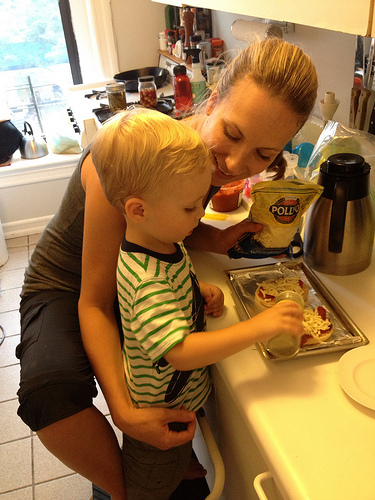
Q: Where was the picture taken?
A: It was taken at the kitchen.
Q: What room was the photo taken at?
A: It was taken at the kitchen.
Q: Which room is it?
A: It is a kitchen.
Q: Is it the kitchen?
A: Yes, it is the kitchen.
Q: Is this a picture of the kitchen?
A: Yes, it is showing the kitchen.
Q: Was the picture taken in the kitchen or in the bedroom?
A: It was taken at the kitchen.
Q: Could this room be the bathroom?
A: No, it is the kitchen.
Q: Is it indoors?
A: Yes, it is indoors.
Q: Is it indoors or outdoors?
A: It is indoors.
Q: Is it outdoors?
A: No, it is indoors.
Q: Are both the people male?
A: No, they are both male and female.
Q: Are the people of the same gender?
A: No, they are both male and female.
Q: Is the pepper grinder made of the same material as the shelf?
A: Yes, both the pepper grinder and the shelf are made of wood.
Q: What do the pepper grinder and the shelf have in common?
A: The material, both the pepper grinder and the shelf are wooden.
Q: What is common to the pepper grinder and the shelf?
A: The material, both the pepper grinder and the shelf are wooden.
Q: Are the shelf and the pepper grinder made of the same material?
A: Yes, both the shelf and the pepper grinder are made of wood.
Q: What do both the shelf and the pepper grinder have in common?
A: The material, both the shelf and the pepper grinder are wooden.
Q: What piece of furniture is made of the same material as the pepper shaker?
A: The shelf is made of the same material as the pepper shaker.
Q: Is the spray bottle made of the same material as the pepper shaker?
A: No, the spray bottle is made of plastic and the pepper shaker is made of wood.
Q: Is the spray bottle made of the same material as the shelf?
A: No, the spray bottle is made of plastic and the shelf is made of wood.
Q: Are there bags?
A: Yes, there is a bag.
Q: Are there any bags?
A: Yes, there is a bag.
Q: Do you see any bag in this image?
A: Yes, there is a bag.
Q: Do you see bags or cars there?
A: Yes, there is a bag.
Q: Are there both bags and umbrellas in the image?
A: No, there is a bag but no umbrellas.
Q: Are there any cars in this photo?
A: No, there are no cars.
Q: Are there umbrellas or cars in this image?
A: No, there are no cars or umbrellas.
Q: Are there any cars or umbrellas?
A: No, there are no cars or umbrellas.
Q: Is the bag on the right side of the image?
A: Yes, the bag is on the right of the image.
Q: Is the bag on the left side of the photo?
A: No, the bag is on the right of the image.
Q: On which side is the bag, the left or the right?
A: The bag is on the right of the image.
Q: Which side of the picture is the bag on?
A: The bag is on the right of the image.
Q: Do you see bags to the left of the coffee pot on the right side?
A: Yes, there is a bag to the left of the coffee pot.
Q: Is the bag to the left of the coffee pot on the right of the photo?
A: Yes, the bag is to the left of the coffee pot.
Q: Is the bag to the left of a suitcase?
A: No, the bag is to the left of the coffee pot.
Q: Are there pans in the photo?
A: Yes, there is a pan.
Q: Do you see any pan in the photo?
A: Yes, there is a pan.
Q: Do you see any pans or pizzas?
A: Yes, there is a pan.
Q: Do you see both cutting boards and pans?
A: No, there is a pan but no cutting boards.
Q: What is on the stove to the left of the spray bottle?
A: The pan is on the stove.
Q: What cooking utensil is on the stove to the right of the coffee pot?
A: The cooking utensil is a pan.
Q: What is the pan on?
A: The pan is on the stove.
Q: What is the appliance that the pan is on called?
A: The appliance is a stove.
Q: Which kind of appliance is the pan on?
A: The pan is on the stove.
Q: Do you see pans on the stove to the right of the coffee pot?
A: Yes, there is a pan on the stove.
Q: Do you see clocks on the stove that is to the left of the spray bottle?
A: No, there is a pan on the stove.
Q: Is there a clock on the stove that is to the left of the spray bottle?
A: No, there is a pan on the stove.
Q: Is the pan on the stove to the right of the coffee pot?
A: Yes, the pan is on the stove.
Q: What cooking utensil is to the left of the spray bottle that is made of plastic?
A: The cooking utensil is a pan.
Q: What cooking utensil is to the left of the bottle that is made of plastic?
A: The cooking utensil is a pan.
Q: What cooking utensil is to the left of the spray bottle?
A: The cooking utensil is a pan.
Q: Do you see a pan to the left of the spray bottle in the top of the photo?
A: Yes, there is a pan to the left of the spray bottle.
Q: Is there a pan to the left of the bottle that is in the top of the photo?
A: Yes, there is a pan to the left of the spray bottle.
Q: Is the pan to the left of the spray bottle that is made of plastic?
A: Yes, the pan is to the left of the spray bottle.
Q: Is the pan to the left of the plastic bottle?
A: Yes, the pan is to the left of the spray bottle.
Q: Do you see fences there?
A: No, there are no fences.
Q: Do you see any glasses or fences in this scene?
A: No, there are no fences or glasses.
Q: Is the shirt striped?
A: Yes, the shirt is striped.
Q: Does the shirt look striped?
A: Yes, the shirt is striped.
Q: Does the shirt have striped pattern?
A: Yes, the shirt is striped.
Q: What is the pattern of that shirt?
A: The shirt is striped.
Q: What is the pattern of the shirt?
A: The shirt is striped.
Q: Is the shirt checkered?
A: No, the shirt is striped.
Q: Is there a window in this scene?
A: Yes, there is a window.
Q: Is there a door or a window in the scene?
A: Yes, there is a window.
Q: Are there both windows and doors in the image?
A: No, there is a window but no doors.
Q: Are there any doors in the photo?
A: No, there are no doors.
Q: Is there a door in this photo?
A: No, there are no doors.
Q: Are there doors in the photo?
A: No, there are no doors.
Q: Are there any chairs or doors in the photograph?
A: No, there are no doors or chairs.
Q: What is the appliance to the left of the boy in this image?
A: The appliance is a stove.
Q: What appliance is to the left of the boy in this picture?
A: The appliance is a stove.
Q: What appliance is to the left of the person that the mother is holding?
A: The appliance is a stove.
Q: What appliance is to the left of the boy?
A: The appliance is a stove.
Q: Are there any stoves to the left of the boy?
A: Yes, there is a stove to the left of the boy.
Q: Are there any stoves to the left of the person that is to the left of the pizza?
A: Yes, there is a stove to the left of the boy.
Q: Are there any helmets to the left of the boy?
A: No, there is a stove to the left of the boy.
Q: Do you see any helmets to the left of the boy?
A: No, there is a stove to the left of the boy.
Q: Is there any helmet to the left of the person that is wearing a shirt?
A: No, there is a stove to the left of the boy.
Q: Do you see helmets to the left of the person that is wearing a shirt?
A: No, there is a stove to the left of the boy.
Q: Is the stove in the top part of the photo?
A: Yes, the stove is in the top of the image.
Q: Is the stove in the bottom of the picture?
A: No, the stove is in the top of the image.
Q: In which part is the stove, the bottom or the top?
A: The stove is in the top of the image.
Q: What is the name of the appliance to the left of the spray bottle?
A: The appliance is a stove.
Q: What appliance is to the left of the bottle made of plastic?
A: The appliance is a stove.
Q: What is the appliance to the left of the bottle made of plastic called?
A: The appliance is a stove.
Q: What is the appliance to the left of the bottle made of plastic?
A: The appliance is a stove.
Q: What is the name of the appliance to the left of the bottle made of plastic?
A: The appliance is a stove.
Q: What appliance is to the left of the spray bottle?
A: The appliance is a stove.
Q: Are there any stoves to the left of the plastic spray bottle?
A: Yes, there is a stove to the left of the spray bottle.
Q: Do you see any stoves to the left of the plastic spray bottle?
A: Yes, there is a stove to the left of the spray bottle.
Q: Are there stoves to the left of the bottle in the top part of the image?
A: Yes, there is a stove to the left of the spray bottle.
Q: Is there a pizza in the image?
A: Yes, there is a pizza.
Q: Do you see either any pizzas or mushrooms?
A: Yes, there is a pizza.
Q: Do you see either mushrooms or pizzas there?
A: Yes, there is a pizza.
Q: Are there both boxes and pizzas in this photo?
A: No, there is a pizza but no boxes.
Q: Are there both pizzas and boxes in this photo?
A: No, there is a pizza but no boxes.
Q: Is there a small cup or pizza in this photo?
A: Yes, there is a small pizza.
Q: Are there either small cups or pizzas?
A: Yes, there is a small pizza.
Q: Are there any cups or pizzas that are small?
A: Yes, the pizza is small.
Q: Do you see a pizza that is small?
A: Yes, there is a small pizza.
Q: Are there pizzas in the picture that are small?
A: Yes, there is a pizza that is small.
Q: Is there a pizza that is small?
A: Yes, there is a pizza that is small.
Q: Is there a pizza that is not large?
A: Yes, there is a small pizza.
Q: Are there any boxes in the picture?
A: No, there are no boxes.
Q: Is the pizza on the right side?
A: Yes, the pizza is on the right of the image.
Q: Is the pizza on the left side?
A: No, the pizza is on the right of the image.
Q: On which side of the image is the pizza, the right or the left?
A: The pizza is on the right of the image.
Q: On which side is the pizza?
A: The pizza is on the right of the image.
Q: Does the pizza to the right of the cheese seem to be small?
A: Yes, the pizza is small.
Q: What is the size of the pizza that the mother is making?
A: The pizza is small.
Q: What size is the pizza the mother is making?
A: The pizza is small.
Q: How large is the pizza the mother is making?
A: The pizza is small.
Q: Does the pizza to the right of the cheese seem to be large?
A: No, the pizza is small.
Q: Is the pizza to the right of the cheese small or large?
A: The pizza is small.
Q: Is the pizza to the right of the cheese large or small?
A: The pizza is small.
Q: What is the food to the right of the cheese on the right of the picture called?
A: The food is a pizza.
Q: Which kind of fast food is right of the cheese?
A: The food is a pizza.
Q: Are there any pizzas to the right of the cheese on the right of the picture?
A: Yes, there is a pizza to the right of the cheese.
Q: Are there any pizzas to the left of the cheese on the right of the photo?
A: No, the pizza is to the right of the cheese.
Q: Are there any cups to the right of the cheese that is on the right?
A: No, there is a pizza to the right of the cheese.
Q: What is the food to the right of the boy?
A: The food is a pizza.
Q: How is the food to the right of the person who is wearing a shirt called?
A: The food is a pizza.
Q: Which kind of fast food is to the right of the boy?
A: The food is a pizza.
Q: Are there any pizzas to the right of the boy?
A: Yes, there is a pizza to the right of the boy.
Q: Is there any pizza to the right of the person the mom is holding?
A: Yes, there is a pizza to the right of the boy.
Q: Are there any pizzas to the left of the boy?
A: No, the pizza is to the right of the boy.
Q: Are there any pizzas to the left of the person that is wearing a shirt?
A: No, the pizza is to the right of the boy.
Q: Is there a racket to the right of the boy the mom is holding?
A: No, there is a pizza to the right of the boy.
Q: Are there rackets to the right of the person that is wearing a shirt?
A: No, there is a pizza to the right of the boy.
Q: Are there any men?
A: No, there are no men.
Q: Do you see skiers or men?
A: No, there are no men or skiers.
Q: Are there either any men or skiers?
A: No, there are no men or skiers.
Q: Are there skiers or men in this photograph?
A: No, there are no men or skiers.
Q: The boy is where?
A: The boy is in the kitchen.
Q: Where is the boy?
A: The boy is in the kitchen.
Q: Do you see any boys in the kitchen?
A: Yes, there is a boy in the kitchen.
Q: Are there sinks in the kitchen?
A: No, there is a boy in the kitchen.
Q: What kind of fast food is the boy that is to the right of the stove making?
A: The boy is making the pizza.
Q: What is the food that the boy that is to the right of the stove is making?
A: The food is a pizza.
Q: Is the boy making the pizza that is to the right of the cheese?
A: Yes, the boy is making the pizza.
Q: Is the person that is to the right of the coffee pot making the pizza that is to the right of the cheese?
A: Yes, the boy is making the pizza.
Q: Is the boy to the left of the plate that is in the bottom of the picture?
A: Yes, the boy is to the left of the plate.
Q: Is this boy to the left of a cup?
A: No, the boy is to the left of the plate.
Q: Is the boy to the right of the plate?
A: No, the boy is to the left of the plate.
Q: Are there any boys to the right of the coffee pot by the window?
A: Yes, there is a boy to the right of the coffee pot.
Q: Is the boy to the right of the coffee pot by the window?
A: Yes, the boy is to the right of the coffee pot.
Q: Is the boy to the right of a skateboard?
A: No, the boy is to the right of the coffee pot.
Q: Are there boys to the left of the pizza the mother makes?
A: Yes, there is a boy to the left of the pizza.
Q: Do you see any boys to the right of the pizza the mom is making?
A: No, the boy is to the left of the pizza.